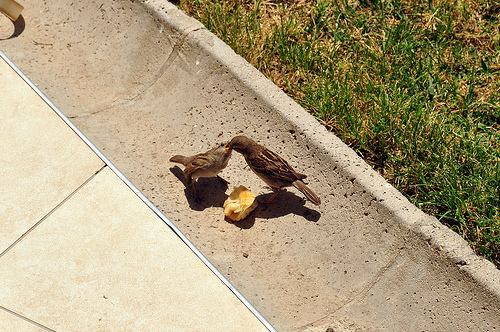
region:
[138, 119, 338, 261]
two birds are kissing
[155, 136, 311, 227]
two birds are kissing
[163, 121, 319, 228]
two small brown birds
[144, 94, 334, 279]
two small brown birds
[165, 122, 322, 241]
birds on a curb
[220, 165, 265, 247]
piece of bread by birds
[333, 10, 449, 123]
green grass on the ground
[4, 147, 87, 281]
separation in the concreter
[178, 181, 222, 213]
shadow of a bird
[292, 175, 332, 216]
tail of a bird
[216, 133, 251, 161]
heads of two birds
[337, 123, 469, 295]
concrete curbing by the grass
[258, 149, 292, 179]
feathers of a bird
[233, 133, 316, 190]
A brown bird on the ground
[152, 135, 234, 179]
A brown bird on the ground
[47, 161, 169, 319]
A cream tile ground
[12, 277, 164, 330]
A cream tile ground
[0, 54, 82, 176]
A cream tile ground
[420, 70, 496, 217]
A green grass field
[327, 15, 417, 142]
A green grass field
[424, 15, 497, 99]
A green grass field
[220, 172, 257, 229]
A yellow little bird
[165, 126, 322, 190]
two birds feeding on the ground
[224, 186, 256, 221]
A piece of food on the ground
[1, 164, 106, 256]
A crack in the sidewalk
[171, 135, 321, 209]
Two birds on the sidewalk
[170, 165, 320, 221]
A shadow on the ground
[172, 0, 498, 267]
Grass by the sidewalk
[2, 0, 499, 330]
The sidewalk beneath the birds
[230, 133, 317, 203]
The bird has brown feathers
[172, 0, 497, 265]
Green grass near the brown birds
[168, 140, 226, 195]
The bird is small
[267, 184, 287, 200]
The legs of the bird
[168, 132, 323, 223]
Two brown birds in a gutter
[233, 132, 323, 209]
A brown bird standing in a gutter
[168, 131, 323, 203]
A brown bird feeds another bird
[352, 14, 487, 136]
Dark green grass of a yard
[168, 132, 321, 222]
Two small birds standing next to food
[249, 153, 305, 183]
Wing of a small bird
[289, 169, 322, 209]
Tail feathers of a small, brown bird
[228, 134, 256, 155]
Head of a small, brown bird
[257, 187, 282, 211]
Talons of a small bird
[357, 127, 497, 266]
Green grass next to a concrete gutter